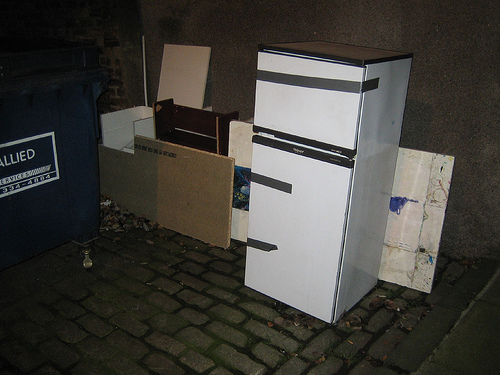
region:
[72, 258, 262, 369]
the ground is tiled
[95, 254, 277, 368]
the ground is tiled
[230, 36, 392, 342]
the fridge is white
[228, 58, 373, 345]
the fridge is white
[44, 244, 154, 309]
section of a dirty floor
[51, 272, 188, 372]
section of a dirty floor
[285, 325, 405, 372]
section of a dirty floor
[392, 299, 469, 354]
section of a dirty floor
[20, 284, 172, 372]
section of a dirty floor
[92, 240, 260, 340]
section of a dirty floor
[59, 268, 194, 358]
section of a dirty floor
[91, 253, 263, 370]
section of a dirty floor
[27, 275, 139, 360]
section of a dirty floor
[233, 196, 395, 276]
Part of a fridge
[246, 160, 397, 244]
Part of a fridge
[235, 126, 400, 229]
Part of a fridge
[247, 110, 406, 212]
Part of a fridge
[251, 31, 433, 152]
Part of a fridge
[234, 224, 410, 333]
Part of a fridge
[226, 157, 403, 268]
Part of a fridge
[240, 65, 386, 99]
the tape is gray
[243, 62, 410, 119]
the tape is gray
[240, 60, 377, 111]
the tape is gray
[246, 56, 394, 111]
the tape is gray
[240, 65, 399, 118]
the tape is gray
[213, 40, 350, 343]
fridge's door is taped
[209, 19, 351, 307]
fridge's door is taped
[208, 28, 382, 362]
fridge's door is taped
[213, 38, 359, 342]
fridge's door is taped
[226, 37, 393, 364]
fridge's door is taped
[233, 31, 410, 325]
white and black fridge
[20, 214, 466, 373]
gray brick walkway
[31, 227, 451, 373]
dark grout between gray bricks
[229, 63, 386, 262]
duct tape on fridge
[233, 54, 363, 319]
two doors on the fridge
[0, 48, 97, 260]
large blue trash container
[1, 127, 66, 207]
white logo on trash container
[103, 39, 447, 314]
debris stacked next to trash container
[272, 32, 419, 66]
black top of the fridge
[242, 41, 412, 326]
white fridge with black trim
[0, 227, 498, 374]
brown brick stone floor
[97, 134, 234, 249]
a piece of wood with a notch cut out of it